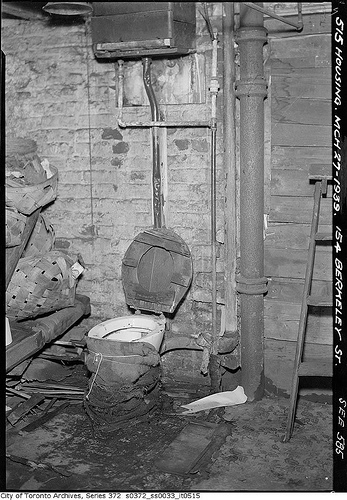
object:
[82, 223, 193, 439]
toilet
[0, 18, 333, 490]
room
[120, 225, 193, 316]
lid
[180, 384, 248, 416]
paper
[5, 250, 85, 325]
basket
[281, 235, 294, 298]
wall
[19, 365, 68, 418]
wood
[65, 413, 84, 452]
floor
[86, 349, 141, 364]
cord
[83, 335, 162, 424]
bag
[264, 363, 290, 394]
wall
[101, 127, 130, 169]
stains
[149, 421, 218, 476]
floor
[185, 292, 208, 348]
wall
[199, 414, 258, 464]
ground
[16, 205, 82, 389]
trash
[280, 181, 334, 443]
ladder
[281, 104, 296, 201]
wall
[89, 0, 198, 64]
box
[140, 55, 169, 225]
pipe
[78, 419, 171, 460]
dirt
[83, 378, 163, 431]
toilet bottom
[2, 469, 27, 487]
photographer watermark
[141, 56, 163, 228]
pipe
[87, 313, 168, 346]
toilet seat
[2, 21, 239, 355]
wall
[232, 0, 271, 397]
drain pipe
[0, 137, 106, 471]
debris pile